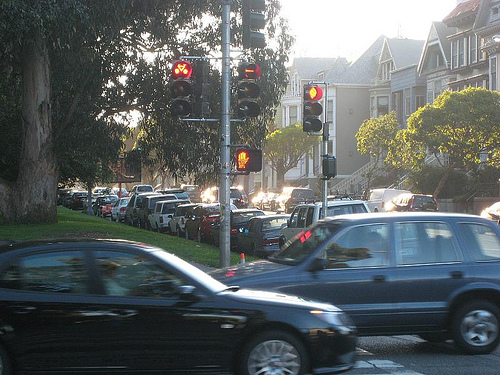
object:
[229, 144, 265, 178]
signal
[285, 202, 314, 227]
window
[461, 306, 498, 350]
wheel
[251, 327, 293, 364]
wheel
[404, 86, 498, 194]
tree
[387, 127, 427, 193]
tree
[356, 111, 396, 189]
tree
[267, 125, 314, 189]
tree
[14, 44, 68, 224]
tree trunk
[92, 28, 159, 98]
leaves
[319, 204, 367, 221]
window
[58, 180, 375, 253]
parked cars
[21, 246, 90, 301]
window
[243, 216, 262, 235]
window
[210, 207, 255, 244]
car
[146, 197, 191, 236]
car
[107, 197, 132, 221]
car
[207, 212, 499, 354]
car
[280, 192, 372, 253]
car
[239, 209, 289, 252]
car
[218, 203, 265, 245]
car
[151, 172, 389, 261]
street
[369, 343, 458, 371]
road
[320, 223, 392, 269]
window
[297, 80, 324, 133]
light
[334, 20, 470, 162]
large houses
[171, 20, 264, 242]
signs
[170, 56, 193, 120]
light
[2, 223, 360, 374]
car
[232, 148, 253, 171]
hand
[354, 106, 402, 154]
leaves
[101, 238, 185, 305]
window